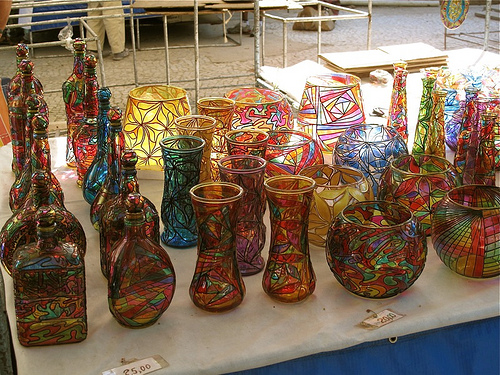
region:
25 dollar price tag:
[99, 355, 169, 374]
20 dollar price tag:
[357, 306, 404, 331]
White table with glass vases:
[0, 45, 499, 374]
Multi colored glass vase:
[12, 205, 87, 347]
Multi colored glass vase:
[105, 192, 175, 329]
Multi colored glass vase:
[187, 180, 244, 312]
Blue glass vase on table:
[159, 135, 206, 250]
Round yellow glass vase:
[120, 82, 190, 168]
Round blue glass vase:
[333, 121, 406, 202]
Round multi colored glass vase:
[324, 198, 427, 300]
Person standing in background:
[81, 1, 131, 62]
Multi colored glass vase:
[261, 175, 316, 302]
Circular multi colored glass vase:
[325, 201, 427, 299]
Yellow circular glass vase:
[120, 83, 192, 171]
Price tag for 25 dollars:
[104, 355, 168, 374]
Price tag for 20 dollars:
[355, 307, 405, 332]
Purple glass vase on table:
[217, 154, 264, 276]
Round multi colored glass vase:
[429, 183, 499, 278]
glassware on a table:
[4, 213, 97, 353]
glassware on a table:
[89, 206, 208, 354]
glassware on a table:
[187, 178, 259, 310]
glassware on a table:
[247, 156, 337, 316]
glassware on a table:
[317, 197, 437, 305]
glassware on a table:
[427, 172, 497, 292]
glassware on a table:
[152, 133, 232, 250]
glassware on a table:
[68, 92, 136, 212]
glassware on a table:
[108, 67, 210, 176]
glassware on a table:
[346, 45, 433, 189]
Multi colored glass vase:
[324, 199, 427, 301]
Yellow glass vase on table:
[121, 83, 193, 171]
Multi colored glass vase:
[297, 72, 365, 154]